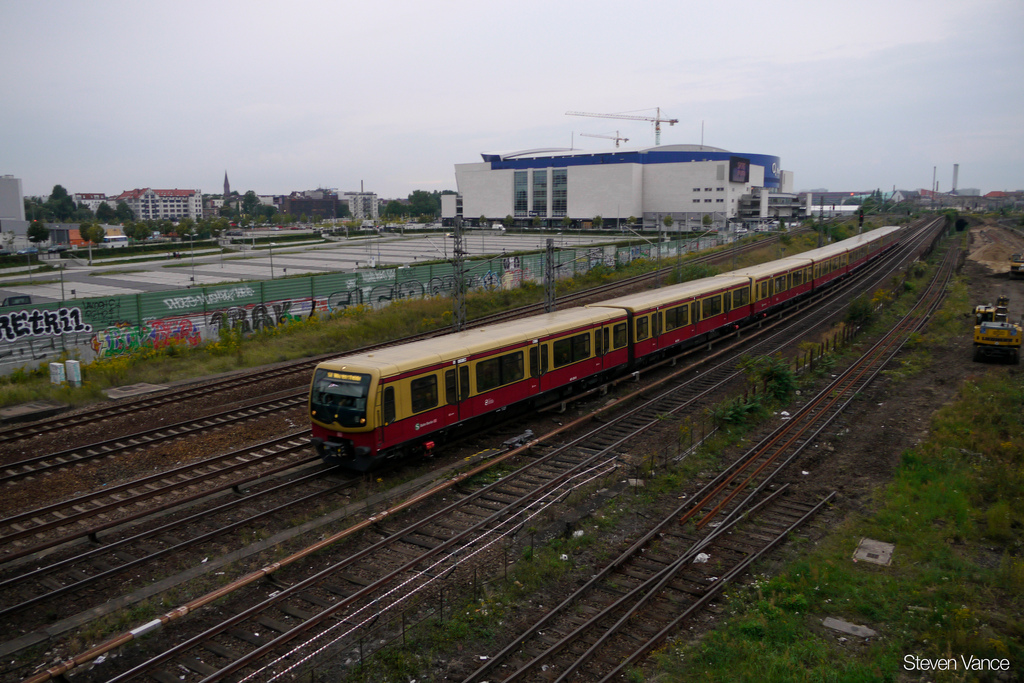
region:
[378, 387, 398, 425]
side window on yellow train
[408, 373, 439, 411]
side window on yellow train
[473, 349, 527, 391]
side window on yellow train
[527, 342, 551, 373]
side window on yellow train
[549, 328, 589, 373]
side window on yellow train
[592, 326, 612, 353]
side window on yellow train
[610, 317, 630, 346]
side window on yellow train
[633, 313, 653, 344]
side window on yellow train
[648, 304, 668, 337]
side window on yellow train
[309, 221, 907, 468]
A long yellow train on train tracks.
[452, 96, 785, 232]
A large blue and white building.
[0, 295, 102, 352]
Black and white spray paint lettering.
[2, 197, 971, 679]
A large wet of train tracks near a factory.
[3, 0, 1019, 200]
A cloud filled gray and white sky.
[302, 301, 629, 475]
A train car on the front end of a train.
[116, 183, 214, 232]
A white building with a brown roof top.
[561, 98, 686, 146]
A crane sitting on top of a building.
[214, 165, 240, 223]
A very tall tree near a building.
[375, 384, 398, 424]
window on yellow train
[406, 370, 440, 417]
window on yellow train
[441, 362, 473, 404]
window on yellow train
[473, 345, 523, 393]
window on yellow train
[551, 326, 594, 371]
window on yellow train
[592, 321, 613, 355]
window on yellow train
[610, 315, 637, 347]
window on yellow train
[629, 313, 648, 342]
window on yellow train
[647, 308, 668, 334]
window on yellow train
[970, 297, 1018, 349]
a tractor next to the tracks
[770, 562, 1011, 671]
grass next to the tracks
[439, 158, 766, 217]
a large white and blue building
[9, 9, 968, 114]
clouds in the sky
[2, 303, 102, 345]
writing on the wall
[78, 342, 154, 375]
yellow flowers on the ground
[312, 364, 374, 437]
front window on train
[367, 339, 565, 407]
windows on the train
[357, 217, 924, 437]
yellow trim on train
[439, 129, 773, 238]
building in the background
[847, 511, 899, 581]
patch in the grass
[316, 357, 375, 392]
sign on the train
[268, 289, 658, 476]
yellow and red passenger train car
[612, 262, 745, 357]
yellow and red passenger train car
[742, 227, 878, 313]
yellow and red passenger train car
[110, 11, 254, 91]
white clouds in blue sky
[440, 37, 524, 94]
white clouds in blue sky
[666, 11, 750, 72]
white clouds in blue sky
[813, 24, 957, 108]
white clouds in blue sky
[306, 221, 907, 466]
a long yellow and red train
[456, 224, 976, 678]
a set of empty train tracks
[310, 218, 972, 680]
vegetation growing between railroad tracks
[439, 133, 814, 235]
large white commercial building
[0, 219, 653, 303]
large empty parking lot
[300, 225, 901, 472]
train with a yellow top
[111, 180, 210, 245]
large building in the distance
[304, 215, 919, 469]
train on the tracks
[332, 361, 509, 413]
windows on the train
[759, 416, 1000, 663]
grass next to tracks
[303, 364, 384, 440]
front window on train